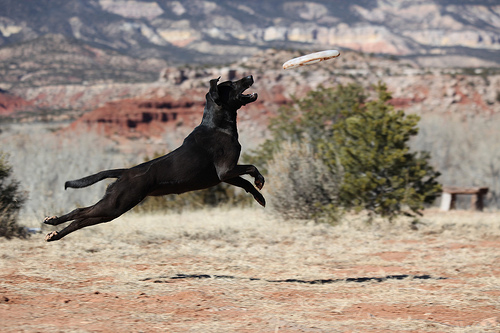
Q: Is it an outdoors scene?
A: Yes, it is outdoors.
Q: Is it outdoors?
A: Yes, it is outdoors.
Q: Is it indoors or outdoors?
A: It is outdoors.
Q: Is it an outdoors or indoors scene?
A: It is outdoors.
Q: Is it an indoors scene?
A: No, it is outdoors.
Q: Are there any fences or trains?
A: No, there are no fences or trains.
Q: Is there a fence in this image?
A: No, there are no fences.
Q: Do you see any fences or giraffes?
A: No, there are no fences or giraffes.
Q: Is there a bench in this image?
A: Yes, there is a bench.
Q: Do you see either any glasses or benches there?
A: Yes, there is a bench.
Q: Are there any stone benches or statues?
A: Yes, there is a stone bench.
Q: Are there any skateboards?
A: No, there are no skateboards.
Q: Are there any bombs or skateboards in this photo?
A: No, there are no skateboards or bombs.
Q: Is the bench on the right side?
A: Yes, the bench is on the right of the image.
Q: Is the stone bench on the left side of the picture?
A: No, the bench is on the right of the image.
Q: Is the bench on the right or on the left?
A: The bench is on the right of the image.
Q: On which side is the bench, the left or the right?
A: The bench is on the right of the image.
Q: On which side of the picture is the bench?
A: The bench is on the right of the image.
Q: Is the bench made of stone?
A: Yes, the bench is made of stone.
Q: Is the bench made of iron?
A: No, the bench is made of stone.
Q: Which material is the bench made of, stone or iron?
A: The bench is made of stone.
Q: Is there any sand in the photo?
A: Yes, there is sand.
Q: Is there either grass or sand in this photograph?
A: Yes, there is sand.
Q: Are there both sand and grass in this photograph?
A: Yes, there are both sand and grass.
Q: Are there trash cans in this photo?
A: No, there are no trash cans.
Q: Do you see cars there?
A: No, there are no cars.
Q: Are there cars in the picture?
A: No, there are no cars.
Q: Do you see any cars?
A: No, there are no cars.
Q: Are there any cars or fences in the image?
A: No, there are no cars or fences.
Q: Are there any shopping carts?
A: No, there are no shopping carts.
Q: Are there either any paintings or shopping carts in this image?
A: No, there are no shopping carts or paintings.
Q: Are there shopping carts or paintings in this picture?
A: No, there are no shopping carts or paintings.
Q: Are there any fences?
A: No, there are no fences.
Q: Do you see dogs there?
A: Yes, there is a dog.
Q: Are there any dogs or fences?
A: Yes, there is a dog.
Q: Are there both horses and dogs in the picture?
A: No, there is a dog but no horses.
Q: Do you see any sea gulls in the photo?
A: No, there are no sea gulls.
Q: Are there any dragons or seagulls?
A: No, there are no seagulls or dragons.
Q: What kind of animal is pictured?
A: The animal is a dog.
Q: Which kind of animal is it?
A: The animal is a dog.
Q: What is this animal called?
A: This is a dog.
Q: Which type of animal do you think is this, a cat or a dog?
A: This is a dog.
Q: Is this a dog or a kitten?
A: This is a dog.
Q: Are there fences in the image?
A: No, there are no fences.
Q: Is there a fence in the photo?
A: No, there are no fences.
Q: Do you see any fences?
A: No, there are no fences.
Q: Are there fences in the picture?
A: No, there are no fences.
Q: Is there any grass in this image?
A: Yes, there is grass.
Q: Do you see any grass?
A: Yes, there is grass.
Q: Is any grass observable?
A: Yes, there is grass.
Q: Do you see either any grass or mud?
A: Yes, there is grass.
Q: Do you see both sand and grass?
A: Yes, there are both grass and sand.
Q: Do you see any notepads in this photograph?
A: No, there are no notepads.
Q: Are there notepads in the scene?
A: No, there are no notepads.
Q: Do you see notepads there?
A: No, there are no notepads.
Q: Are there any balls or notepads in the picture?
A: No, there are no notepads or balls.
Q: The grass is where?
A: The grass is on the ground.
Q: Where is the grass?
A: The grass is on the ground.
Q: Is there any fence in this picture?
A: No, there are no fences.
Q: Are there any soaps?
A: No, there are no soaps.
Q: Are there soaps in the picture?
A: No, there are no soaps.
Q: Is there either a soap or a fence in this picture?
A: No, there are no soaps or fences.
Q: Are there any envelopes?
A: No, there are no envelopes.